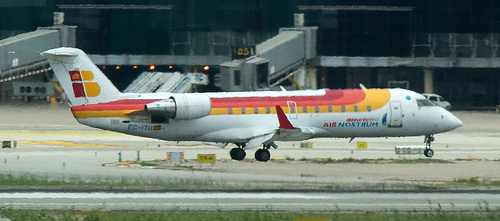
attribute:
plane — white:
[31, 43, 468, 161]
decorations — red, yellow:
[65, 63, 397, 123]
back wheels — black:
[227, 140, 279, 167]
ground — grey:
[0, 98, 500, 219]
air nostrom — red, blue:
[322, 118, 383, 131]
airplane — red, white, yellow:
[39, 45, 472, 168]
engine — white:
[133, 88, 213, 122]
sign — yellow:
[197, 152, 218, 165]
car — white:
[420, 88, 452, 111]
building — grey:
[1, 1, 499, 96]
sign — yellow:
[355, 139, 370, 154]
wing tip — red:
[269, 102, 299, 134]